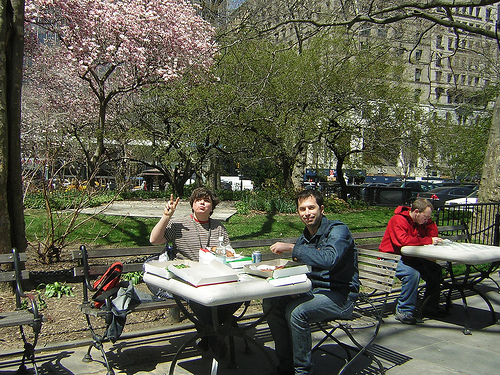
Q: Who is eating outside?
A: Two men.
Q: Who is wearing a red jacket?
A: Man at far right.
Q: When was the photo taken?
A: Sunny day.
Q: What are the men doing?
A: Eating.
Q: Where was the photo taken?
A: In a park.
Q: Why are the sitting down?
A: Eating.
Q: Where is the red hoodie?
A: On the man alone at a table.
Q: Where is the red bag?
A: On the bench next to the man in the striped shirt.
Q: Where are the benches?
A: In the park.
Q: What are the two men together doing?
A: Eating.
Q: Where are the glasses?
A: On the man in the red hoodie.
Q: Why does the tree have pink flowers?
A: Cherry blossom.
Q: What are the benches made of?
A: Wood and metal.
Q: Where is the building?
A: Behind the park.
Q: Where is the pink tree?
A: On the left.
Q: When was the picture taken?
A: Daytime.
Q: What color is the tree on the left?
A: Pink.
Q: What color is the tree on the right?
A: Green.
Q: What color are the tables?
A: White.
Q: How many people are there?
A: Three.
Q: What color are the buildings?
A: Gray.